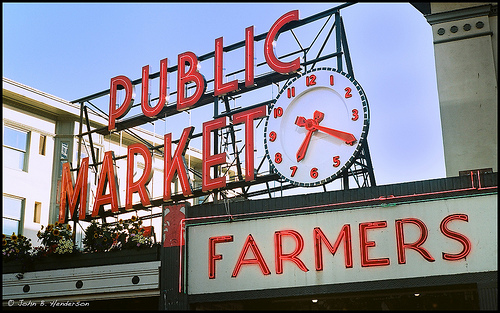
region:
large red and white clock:
[252, 67, 387, 183]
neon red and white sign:
[215, 227, 456, 295]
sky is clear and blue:
[53, 27, 205, 83]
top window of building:
[5, 105, 38, 182]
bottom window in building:
[5, 195, 42, 260]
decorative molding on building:
[417, 8, 499, 53]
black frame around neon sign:
[181, 168, 488, 208]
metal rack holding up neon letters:
[63, 71, 120, 163]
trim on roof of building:
[10, 73, 73, 108]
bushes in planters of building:
[38, 222, 141, 261]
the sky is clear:
[11, 21, 73, 44]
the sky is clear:
[22, 23, 97, 80]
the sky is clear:
[22, 7, 174, 144]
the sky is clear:
[37, 31, 74, 67]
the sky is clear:
[15, 11, 113, 109]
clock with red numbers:
[257, 61, 382, 193]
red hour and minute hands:
[243, 57, 380, 189]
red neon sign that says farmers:
[183, 205, 499, 296]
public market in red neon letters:
[37, 5, 304, 219]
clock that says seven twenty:
[260, 48, 386, 202]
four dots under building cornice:
[417, 2, 499, 42]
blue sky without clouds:
[12, 14, 123, 74]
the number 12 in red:
[301, 67, 320, 89]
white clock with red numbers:
[245, 57, 387, 212]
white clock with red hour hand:
[251, 64, 381, 193]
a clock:
[216, 31, 447, 276]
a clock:
[232, 70, 402, 229]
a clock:
[195, 52, 349, 174]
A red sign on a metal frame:
[42, 7, 499, 290]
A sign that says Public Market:
[42, 8, 391, 229]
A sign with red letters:
[172, 198, 492, 295]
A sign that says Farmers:
[167, 200, 497, 290]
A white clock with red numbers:
[262, 65, 373, 200]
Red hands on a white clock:
[290, 108, 358, 166]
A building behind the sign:
[9, 64, 252, 266]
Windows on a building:
[0, 63, 58, 253]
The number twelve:
[301, 69, 320, 92]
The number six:
[305, 163, 324, 185]